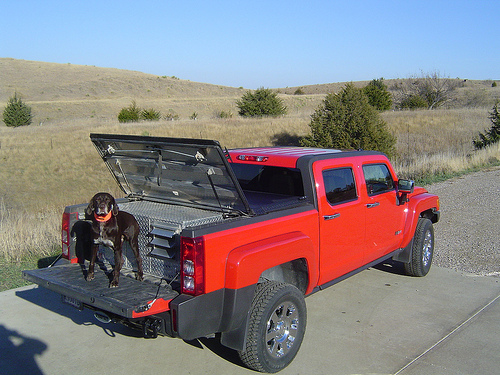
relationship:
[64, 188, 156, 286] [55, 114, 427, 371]
dog on truck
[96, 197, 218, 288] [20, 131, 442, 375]
bin on truck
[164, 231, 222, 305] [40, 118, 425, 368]
light on pickup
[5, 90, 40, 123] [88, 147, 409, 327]
bush by truck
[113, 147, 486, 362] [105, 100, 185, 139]
truck by bush